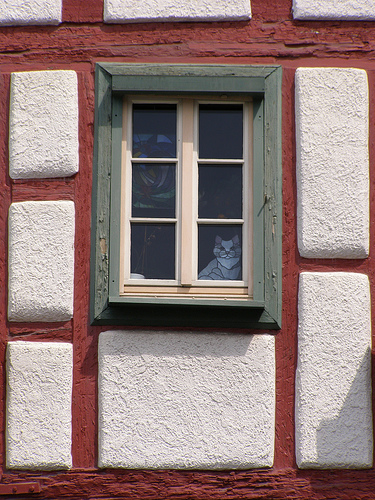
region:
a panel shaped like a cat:
[203, 235, 241, 276]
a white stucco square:
[109, 342, 264, 458]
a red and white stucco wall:
[19, 326, 358, 450]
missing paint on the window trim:
[94, 235, 109, 255]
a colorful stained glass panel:
[132, 130, 190, 225]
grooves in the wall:
[119, 471, 294, 498]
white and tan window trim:
[179, 97, 196, 285]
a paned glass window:
[131, 105, 245, 279]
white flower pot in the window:
[129, 265, 148, 279]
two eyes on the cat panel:
[220, 244, 239, 250]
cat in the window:
[196, 224, 241, 278]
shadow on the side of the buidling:
[304, 355, 370, 463]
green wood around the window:
[89, 65, 289, 329]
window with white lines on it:
[124, 108, 247, 288]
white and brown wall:
[0, 0, 372, 497]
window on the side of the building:
[86, 64, 289, 330]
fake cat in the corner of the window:
[199, 232, 249, 281]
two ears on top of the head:
[213, 230, 240, 243]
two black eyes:
[217, 243, 237, 254]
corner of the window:
[121, 268, 143, 287]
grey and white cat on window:
[198, 233, 243, 279]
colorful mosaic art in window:
[132, 130, 181, 211]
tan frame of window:
[120, 92, 255, 302]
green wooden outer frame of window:
[87, 58, 283, 332]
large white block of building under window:
[96, 331, 277, 471]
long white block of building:
[293, 269, 374, 469]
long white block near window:
[293, 64, 374, 260]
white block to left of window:
[6, 197, 75, 323]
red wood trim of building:
[0, 0, 372, 497]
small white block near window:
[7, 69, 79, 181]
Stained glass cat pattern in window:
[197, 224, 240, 282]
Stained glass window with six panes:
[94, 61, 280, 327]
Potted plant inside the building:
[130, 223, 157, 280]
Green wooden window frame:
[94, 59, 279, 331]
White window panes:
[121, 94, 251, 298]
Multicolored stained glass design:
[132, 133, 177, 208]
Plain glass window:
[199, 104, 241, 159]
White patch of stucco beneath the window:
[96, 327, 275, 468]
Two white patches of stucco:
[293, 64, 373, 469]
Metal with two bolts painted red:
[1, 481, 37, 497]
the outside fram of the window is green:
[96, 61, 281, 328]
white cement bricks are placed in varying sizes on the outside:
[10, 71, 75, 173]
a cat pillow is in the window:
[196, 225, 243, 280]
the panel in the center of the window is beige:
[180, 104, 189, 282]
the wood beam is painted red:
[2, 28, 366, 61]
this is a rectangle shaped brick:
[294, 67, 369, 252]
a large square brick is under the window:
[105, 332, 268, 463]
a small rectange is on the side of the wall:
[5, 343, 68, 467]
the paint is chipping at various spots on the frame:
[263, 64, 282, 322]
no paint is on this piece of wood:
[96, 236, 106, 259]